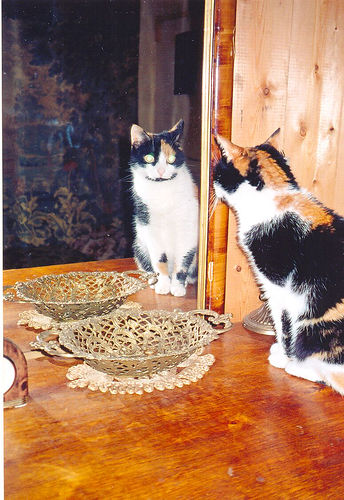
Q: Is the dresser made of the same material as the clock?
A: Yes, both the dresser and the clock are made of wood.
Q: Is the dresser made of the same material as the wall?
A: Yes, both the dresser and the wall are made of wood.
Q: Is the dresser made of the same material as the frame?
A: Yes, both the dresser and the frame are made of wood.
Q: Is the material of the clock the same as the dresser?
A: Yes, both the clock and the dresser are made of wood.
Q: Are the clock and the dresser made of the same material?
A: Yes, both the clock and the dresser are made of wood.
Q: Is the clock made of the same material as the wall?
A: Yes, both the clock and the wall are made of wood.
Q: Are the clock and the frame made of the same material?
A: Yes, both the clock and the frame are made of wood.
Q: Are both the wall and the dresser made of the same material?
A: Yes, both the wall and the dresser are made of wood.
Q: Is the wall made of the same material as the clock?
A: Yes, both the wall and the clock are made of wood.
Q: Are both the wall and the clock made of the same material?
A: Yes, both the wall and the clock are made of wood.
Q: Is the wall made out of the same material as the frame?
A: Yes, both the wall and the frame are made of wood.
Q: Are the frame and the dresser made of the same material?
A: Yes, both the frame and the dresser are made of wood.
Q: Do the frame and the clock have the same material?
A: Yes, both the frame and the clock are made of wood.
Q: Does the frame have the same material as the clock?
A: Yes, both the frame and the clock are made of wood.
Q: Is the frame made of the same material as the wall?
A: Yes, both the frame and the wall are made of wood.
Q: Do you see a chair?
A: No, there are no chairs.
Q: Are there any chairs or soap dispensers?
A: No, there are no chairs or soap dispensers.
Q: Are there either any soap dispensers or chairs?
A: No, there are no chairs or soap dispensers.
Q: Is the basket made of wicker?
A: Yes, the basket is made of wicker.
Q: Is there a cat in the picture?
A: Yes, there is a cat.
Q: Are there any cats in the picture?
A: Yes, there is a cat.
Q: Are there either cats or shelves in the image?
A: Yes, there is a cat.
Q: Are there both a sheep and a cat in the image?
A: No, there is a cat but no sheep.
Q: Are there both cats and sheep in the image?
A: No, there is a cat but no sheep.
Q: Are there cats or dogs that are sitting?
A: Yes, the cat is sitting.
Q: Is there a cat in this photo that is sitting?
A: Yes, there is a cat that is sitting.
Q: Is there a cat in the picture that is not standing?
A: Yes, there is a cat that is sitting.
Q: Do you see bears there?
A: No, there are no bears.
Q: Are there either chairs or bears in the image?
A: No, there are no bears or chairs.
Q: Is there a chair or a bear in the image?
A: No, there are no bears or chairs.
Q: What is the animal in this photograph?
A: The animal is a cat.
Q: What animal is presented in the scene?
A: The animal is a cat.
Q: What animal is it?
A: The animal is a cat.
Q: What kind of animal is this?
A: This is a cat.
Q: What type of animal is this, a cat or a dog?
A: This is a cat.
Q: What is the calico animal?
A: The animal is a cat.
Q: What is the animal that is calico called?
A: The animal is a cat.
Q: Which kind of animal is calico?
A: The animal is a cat.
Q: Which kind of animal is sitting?
A: The animal is a cat.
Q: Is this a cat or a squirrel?
A: This is a cat.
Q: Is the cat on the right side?
A: Yes, the cat is on the right of the image.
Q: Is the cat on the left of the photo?
A: No, the cat is on the right of the image.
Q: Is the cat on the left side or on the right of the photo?
A: The cat is on the right of the image.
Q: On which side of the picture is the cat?
A: The cat is on the right of the image.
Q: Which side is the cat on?
A: The cat is on the right of the image.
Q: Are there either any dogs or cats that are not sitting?
A: No, there is a cat but it is sitting.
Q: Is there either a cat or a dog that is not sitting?
A: No, there is a cat but it is sitting.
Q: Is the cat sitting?
A: Yes, the cat is sitting.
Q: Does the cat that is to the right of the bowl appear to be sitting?
A: Yes, the cat is sitting.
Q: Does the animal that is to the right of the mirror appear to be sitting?
A: Yes, the cat is sitting.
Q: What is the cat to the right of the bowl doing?
A: The cat is sitting.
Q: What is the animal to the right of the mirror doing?
A: The cat is sitting.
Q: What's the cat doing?
A: The cat is sitting.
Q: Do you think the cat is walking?
A: No, the cat is sitting.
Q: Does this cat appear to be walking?
A: No, the cat is sitting.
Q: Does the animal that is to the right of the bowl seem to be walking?
A: No, the cat is sitting.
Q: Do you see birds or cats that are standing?
A: No, there is a cat but it is sitting.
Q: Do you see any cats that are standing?
A: No, there is a cat but it is sitting.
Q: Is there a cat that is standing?
A: No, there is a cat but it is sitting.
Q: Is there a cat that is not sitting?
A: No, there is a cat but it is sitting.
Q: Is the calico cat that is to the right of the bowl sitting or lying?
A: The cat is sitting.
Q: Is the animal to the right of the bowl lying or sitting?
A: The cat is sitting.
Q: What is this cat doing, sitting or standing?
A: The cat is sitting.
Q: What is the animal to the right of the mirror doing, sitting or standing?
A: The cat is sitting.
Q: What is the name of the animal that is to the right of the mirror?
A: The animal is a cat.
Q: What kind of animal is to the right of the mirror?
A: The animal is a cat.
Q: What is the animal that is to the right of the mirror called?
A: The animal is a cat.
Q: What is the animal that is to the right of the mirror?
A: The animal is a cat.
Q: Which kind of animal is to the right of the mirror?
A: The animal is a cat.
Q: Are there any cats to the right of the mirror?
A: Yes, there is a cat to the right of the mirror.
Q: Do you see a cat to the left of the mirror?
A: No, the cat is to the right of the mirror.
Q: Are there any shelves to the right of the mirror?
A: No, there is a cat to the right of the mirror.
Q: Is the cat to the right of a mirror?
A: Yes, the cat is to the right of a mirror.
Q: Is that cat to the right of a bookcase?
A: No, the cat is to the right of a mirror.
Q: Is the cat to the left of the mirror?
A: No, the cat is to the right of the mirror.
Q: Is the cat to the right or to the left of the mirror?
A: The cat is to the right of the mirror.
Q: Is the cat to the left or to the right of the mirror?
A: The cat is to the right of the mirror.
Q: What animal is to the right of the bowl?
A: The animal is a cat.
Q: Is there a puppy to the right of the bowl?
A: No, there is a cat to the right of the bowl.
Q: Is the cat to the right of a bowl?
A: Yes, the cat is to the right of a bowl.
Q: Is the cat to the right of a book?
A: No, the cat is to the right of a bowl.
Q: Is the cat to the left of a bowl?
A: No, the cat is to the right of a bowl.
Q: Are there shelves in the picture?
A: No, there are no shelves.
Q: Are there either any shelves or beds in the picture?
A: No, there are no shelves or beds.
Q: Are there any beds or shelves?
A: No, there are no shelves or beds.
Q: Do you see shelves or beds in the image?
A: No, there are no shelves or beds.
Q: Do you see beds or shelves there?
A: No, there are no shelves or beds.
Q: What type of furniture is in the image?
A: The furniture is a dresser.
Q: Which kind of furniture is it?
A: The piece of furniture is a dresser.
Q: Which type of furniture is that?
A: This is a dresser.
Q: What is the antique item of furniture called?
A: The piece of furniture is a dresser.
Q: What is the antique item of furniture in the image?
A: The piece of furniture is a dresser.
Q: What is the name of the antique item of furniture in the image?
A: The piece of furniture is a dresser.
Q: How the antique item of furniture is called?
A: The piece of furniture is a dresser.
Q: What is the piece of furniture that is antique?
A: The piece of furniture is a dresser.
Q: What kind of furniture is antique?
A: The furniture is a dresser.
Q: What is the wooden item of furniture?
A: The piece of furniture is a dresser.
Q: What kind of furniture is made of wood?
A: The furniture is a dresser.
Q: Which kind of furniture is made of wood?
A: The furniture is a dresser.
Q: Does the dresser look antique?
A: Yes, the dresser is antique.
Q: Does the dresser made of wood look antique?
A: Yes, the dresser is antique.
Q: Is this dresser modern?
A: No, the dresser is antique.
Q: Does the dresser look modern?
A: No, the dresser is antique.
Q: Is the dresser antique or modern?
A: The dresser is antique.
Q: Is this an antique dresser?
A: Yes, this is an antique dresser.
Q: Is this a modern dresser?
A: No, this is an antique dresser.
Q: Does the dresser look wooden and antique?
A: Yes, the dresser is wooden and antique.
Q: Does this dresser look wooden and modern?
A: No, the dresser is wooden but antique.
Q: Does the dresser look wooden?
A: Yes, the dresser is wooden.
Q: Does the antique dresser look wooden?
A: Yes, the dresser is wooden.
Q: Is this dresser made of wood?
A: Yes, the dresser is made of wood.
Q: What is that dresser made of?
A: The dresser is made of wood.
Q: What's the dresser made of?
A: The dresser is made of wood.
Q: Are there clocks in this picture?
A: Yes, there is a clock.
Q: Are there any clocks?
A: Yes, there is a clock.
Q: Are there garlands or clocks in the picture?
A: Yes, there is a clock.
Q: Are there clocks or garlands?
A: Yes, there is a clock.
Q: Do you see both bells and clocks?
A: No, there is a clock but no bells.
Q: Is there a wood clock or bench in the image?
A: Yes, there is a wood clock.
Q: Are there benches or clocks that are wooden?
A: Yes, the clock is wooden.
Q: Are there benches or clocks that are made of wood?
A: Yes, the clock is made of wood.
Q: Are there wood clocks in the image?
A: Yes, there is a wood clock.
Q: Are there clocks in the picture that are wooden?
A: Yes, there is a clock that is wooden.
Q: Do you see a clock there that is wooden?
A: Yes, there is a clock that is wooden.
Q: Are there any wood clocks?
A: Yes, there is a clock that is made of wood.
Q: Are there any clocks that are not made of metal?
A: Yes, there is a clock that is made of wood.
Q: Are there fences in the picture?
A: No, there are no fences.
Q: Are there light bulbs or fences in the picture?
A: No, there are no fences or light bulbs.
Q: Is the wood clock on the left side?
A: Yes, the clock is on the left of the image.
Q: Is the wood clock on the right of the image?
A: No, the clock is on the left of the image.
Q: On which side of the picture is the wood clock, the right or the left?
A: The clock is on the left of the image.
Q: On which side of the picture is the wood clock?
A: The clock is on the left of the image.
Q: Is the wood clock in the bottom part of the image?
A: Yes, the clock is in the bottom of the image.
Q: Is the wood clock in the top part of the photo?
A: No, the clock is in the bottom of the image.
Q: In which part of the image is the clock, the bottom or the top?
A: The clock is in the bottom of the image.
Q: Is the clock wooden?
A: Yes, the clock is wooden.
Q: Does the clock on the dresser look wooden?
A: Yes, the clock is wooden.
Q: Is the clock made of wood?
A: Yes, the clock is made of wood.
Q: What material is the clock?
A: The clock is made of wood.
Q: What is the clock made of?
A: The clock is made of wood.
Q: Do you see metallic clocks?
A: No, there is a clock but it is wooden.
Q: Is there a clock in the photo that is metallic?
A: No, there is a clock but it is wooden.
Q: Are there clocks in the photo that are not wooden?
A: No, there is a clock but it is wooden.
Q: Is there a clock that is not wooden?
A: No, there is a clock but it is wooden.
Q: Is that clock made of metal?
A: No, the clock is made of wood.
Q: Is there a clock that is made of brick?
A: No, there is a clock but it is made of wood.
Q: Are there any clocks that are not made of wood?
A: No, there is a clock but it is made of wood.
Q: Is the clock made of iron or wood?
A: The clock is made of wood.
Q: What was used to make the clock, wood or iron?
A: The clock is made of wood.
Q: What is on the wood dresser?
A: The clock is on the dresser.